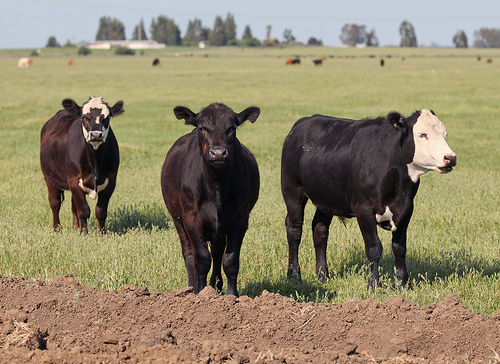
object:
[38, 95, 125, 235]
cow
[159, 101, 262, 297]
cow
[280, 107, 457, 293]
cow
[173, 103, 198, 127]
ear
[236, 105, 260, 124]
ear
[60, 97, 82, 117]
ear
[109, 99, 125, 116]
ear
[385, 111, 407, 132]
ear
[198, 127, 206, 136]
eye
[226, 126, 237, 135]
eye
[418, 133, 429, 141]
eye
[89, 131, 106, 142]
nose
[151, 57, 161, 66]
cow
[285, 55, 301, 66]
cow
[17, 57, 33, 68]
cow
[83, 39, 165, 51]
building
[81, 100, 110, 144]
face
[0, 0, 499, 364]
field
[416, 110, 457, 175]
face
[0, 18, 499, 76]
distance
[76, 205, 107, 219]
knees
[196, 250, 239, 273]
knees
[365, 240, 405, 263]
knees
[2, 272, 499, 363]
dirt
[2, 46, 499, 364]
ground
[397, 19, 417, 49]
tree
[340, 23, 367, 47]
tree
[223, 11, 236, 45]
tree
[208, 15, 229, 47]
tree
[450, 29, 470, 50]
tree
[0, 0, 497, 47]
sky